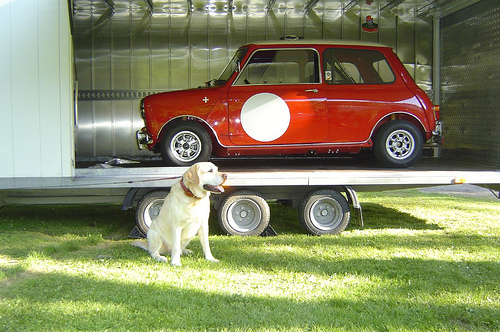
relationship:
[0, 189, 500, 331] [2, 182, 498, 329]
grass on ground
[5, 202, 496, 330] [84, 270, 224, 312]
shadow on grass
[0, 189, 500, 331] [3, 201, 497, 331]
grass on ground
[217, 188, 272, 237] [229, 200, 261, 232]
axel has hubcap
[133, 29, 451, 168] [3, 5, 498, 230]
car in trailer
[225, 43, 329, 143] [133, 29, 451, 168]
door on car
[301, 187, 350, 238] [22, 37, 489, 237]
axel on trailer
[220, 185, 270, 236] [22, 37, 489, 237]
axel on trailer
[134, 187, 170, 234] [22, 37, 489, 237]
axel on trailer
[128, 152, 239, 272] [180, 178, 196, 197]
lab wearing a collar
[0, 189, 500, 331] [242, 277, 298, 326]
grass on t ground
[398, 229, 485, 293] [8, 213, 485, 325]
grass on ground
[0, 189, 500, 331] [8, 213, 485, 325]
grass on ground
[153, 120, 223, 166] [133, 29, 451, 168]
tire on car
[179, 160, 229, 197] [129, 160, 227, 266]
head on dog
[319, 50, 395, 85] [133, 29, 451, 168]
window on car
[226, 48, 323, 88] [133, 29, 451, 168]
side window on car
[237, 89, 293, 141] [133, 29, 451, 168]
circle in car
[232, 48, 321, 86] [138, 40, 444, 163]
side window on car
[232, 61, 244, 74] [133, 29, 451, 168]
mirror on car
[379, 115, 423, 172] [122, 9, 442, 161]
tire on car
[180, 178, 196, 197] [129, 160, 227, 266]
collar on dog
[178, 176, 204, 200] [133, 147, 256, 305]
collar on dog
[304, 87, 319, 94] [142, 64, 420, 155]
handle on car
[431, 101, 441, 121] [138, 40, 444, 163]
light on car